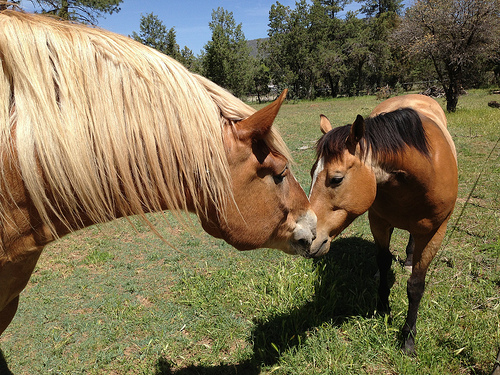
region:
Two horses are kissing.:
[196, 104, 353, 280]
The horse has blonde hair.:
[39, 48, 196, 192]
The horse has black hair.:
[356, 112, 421, 149]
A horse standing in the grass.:
[294, 117, 466, 364]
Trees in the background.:
[203, 12, 425, 96]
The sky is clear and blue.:
[113, 7, 299, 49]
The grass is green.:
[104, 277, 357, 360]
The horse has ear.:
[223, 84, 309, 135]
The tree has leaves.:
[253, 12, 341, 67]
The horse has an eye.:
[303, 142, 350, 190]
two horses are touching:
[181, 103, 433, 293]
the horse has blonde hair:
[37, 80, 312, 242]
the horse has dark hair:
[327, 108, 478, 185]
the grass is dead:
[67, 253, 257, 363]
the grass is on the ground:
[106, 265, 242, 350]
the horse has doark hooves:
[362, 271, 482, 356]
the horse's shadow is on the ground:
[296, 213, 392, 361]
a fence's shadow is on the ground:
[461, 156, 491, 206]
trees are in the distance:
[238, 35, 440, 195]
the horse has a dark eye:
[303, 158, 371, 183]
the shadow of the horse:
[161, 235, 393, 372]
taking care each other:
[139, 65, 425, 278]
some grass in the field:
[81, 285, 216, 333]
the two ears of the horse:
[314, 114, 364, 142]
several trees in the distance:
[207, 7, 432, 86]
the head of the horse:
[190, 91, 319, 250]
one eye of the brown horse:
[265, 159, 290, 182]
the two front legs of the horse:
[371, 219, 436, 351]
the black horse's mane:
[325, 113, 432, 159]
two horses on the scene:
[22, 13, 461, 349]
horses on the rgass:
[2, 58, 374, 257]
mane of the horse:
[30, 68, 250, 183]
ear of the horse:
[239, 74, 288, 136]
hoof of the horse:
[395, 321, 420, 355]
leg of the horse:
[407, 250, 439, 322]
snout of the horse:
[269, 227, 321, 252]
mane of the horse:
[332, 114, 426, 148]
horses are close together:
[8, 39, 493, 341]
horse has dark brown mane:
[327, 112, 434, 166]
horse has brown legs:
[337, 193, 429, 357]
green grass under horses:
[216, 287, 387, 374]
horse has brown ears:
[231, 77, 286, 139]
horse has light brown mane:
[4, 44, 209, 197]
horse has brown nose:
[281, 217, 327, 264]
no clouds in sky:
[172, 7, 200, 44]